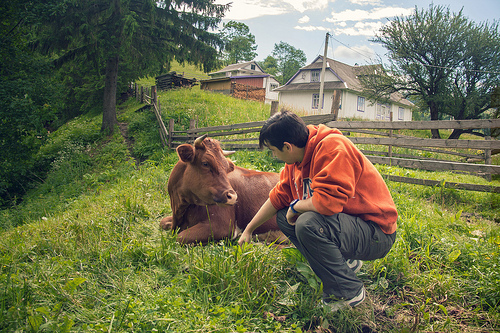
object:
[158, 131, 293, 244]
cow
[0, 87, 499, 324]
ground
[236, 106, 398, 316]
man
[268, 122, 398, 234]
sweatshirt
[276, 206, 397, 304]
pants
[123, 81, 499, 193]
fence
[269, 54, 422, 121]
house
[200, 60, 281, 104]
house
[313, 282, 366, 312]
shoe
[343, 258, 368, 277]
shoe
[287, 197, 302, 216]
watch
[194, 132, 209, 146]
horn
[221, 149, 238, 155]
horn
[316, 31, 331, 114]
utility pole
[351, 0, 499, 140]
tree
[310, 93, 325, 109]
window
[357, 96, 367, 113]
window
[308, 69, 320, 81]
window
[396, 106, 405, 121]
window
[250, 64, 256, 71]
window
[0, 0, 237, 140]
tree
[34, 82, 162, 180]
hill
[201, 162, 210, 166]
eye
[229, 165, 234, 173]
eye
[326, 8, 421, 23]
cloud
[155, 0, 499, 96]
sky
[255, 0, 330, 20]
cloud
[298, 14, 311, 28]
cloud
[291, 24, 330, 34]
cloud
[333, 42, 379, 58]
cloud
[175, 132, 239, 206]
head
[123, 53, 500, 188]
yard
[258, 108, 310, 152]
hair